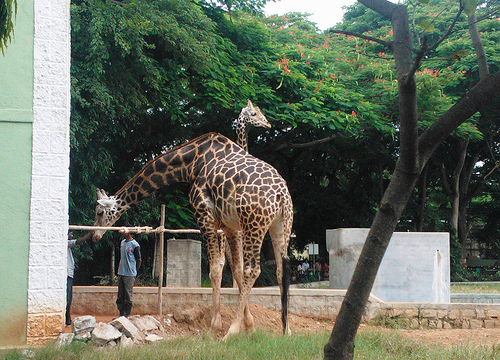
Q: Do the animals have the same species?
A: Yes, all the animals are giraffes.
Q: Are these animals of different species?
A: No, all the animals are giraffes.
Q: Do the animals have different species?
A: No, all the animals are giraffes.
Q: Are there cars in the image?
A: No, there are no cars.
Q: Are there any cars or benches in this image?
A: No, there are no cars or benches.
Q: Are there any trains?
A: No, there are no trains.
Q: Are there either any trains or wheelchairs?
A: No, there are no trains or wheelchairs.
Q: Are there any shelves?
A: No, there are no shelves.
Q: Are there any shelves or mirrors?
A: No, there are no shelves or mirrors.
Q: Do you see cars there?
A: No, there are no cars.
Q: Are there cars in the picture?
A: No, there are no cars.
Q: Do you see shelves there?
A: No, there are no shelves.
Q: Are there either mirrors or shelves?
A: No, there are no shelves or mirrors.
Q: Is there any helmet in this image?
A: No, there are no helmets.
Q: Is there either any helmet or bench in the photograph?
A: No, there are no helmets or benches.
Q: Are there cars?
A: No, there are no cars.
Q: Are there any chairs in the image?
A: No, there are no chairs.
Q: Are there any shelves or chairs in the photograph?
A: No, there are no chairs or shelves.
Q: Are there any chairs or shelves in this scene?
A: No, there are no chairs or shelves.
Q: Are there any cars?
A: No, there are no cars.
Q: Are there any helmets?
A: No, there are no helmets.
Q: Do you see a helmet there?
A: No, there are no helmets.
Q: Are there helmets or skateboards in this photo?
A: No, there are no helmets or skateboards.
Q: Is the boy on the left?
A: Yes, the boy is on the left of the image.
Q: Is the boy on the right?
A: No, the boy is on the left of the image.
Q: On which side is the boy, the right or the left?
A: The boy is on the left of the image.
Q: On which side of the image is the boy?
A: The boy is on the left of the image.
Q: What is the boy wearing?
A: The boy is wearing a shirt.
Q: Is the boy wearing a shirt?
A: Yes, the boy is wearing a shirt.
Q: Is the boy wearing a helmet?
A: No, the boy is wearing a shirt.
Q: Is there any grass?
A: Yes, there is grass.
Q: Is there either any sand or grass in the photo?
A: Yes, there is grass.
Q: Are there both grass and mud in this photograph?
A: No, there is grass but no mud.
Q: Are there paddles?
A: No, there are no paddles.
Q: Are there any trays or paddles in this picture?
A: No, there are no paddles or trays.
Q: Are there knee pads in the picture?
A: No, there are no knee pads.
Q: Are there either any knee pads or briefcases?
A: No, there are no knee pads or briefcases.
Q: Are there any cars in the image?
A: No, there are no cars.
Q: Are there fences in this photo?
A: Yes, there is a fence.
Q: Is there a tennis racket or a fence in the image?
A: Yes, there is a fence.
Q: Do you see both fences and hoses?
A: No, there is a fence but no hoses.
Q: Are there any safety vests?
A: No, there are no safety vests.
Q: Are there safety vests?
A: No, there are no safety vests.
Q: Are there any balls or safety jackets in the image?
A: No, there are no safety jackets or balls.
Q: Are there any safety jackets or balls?
A: No, there are no safety jackets or balls.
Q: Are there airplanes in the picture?
A: No, there are no airplanes.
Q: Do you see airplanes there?
A: No, there are no airplanes.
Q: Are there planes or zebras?
A: No, there are no planes or zebras.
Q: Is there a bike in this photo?
A: No, there are no bikes.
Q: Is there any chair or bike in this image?
A: No, there are no bikes or chairs.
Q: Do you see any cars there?
A: No, there are no cars.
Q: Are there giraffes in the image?
A: Yes, there is a giraffe.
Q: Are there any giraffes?
A: Yes, there is a giraffe.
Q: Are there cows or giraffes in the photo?
A: Yes, there is a giraffe.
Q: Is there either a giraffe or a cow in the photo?
A: Yes, there is a giraffe.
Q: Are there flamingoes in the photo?
A: No, there are no flamingoes.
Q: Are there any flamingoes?
A: No, there are no flamingoes.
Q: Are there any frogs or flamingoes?
A: No, there are no flamingoes or frogs.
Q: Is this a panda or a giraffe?
A: This is a giraffe.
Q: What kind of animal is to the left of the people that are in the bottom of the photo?
A: The animal is a giraffe.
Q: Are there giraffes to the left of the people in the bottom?
A: Yes, there is a giraffe to the left of the people.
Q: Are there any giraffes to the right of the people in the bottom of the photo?
A: No, the giraffe is to the left of the people.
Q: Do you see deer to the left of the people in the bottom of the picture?
A: No, there is a giraffe to the left of the people.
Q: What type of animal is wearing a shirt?
A: The animal is a giraffe.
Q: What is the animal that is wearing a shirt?
A: The animal is a giraffe.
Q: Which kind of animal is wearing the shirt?
A: The animal is a giraffe.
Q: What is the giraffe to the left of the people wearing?
A: The giraffe is wearing a shirt.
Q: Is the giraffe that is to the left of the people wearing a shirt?
A: Yes, the giraffe is wearing a shirt.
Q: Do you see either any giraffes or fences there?
A: Yes, there is a giraffe.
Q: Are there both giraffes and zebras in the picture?
A: No, there is a giraffe but no zebras.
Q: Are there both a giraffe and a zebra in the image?
A: No, there is a giraffe but no zebras.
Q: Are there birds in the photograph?
A: No, there are no birds.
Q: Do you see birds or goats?
A: No, there are no birds or goats.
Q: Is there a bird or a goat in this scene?
A: No, there are no birds or goats.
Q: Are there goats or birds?
A: No, there are no birds or goats.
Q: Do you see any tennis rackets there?
A: No, there are no tennis rackets.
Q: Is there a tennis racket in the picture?
A: No, there are no rackets.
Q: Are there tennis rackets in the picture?
A: No, there are no tennis rackets.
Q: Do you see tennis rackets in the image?
A: No, there are no tennis rackets.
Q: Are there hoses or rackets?
A: No, there are no rackets or hoses.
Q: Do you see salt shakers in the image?
A: No, there are no salt shakers.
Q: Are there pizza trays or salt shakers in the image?
A: No, there are no salt shakers or pizza trays.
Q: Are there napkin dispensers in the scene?
A: No, there are no napkin dispensers.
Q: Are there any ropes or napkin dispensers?
A: No, there are no napkin dispensers or ropes.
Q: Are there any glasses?
A: No, there are no glasses.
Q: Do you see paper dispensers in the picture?
A: No, there are no paper dispensers.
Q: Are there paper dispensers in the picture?
A: No, there are no paper dispensers.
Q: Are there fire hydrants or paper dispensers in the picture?
A: No, there are no paper dispensers or fire hydrants.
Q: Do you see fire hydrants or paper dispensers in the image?
A: No, there are no paper dispensers or fire hydrants.